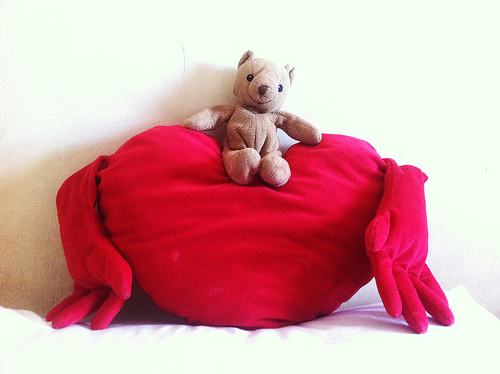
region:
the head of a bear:
[233, 30, 313, 110]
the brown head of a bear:
[205, 58, 296, 140]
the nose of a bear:
[243, 69, 280, 107]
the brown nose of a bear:
[242, 75, 282, 110]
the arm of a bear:
[176, 95, 238, 132]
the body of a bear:
[215, 4, 317, 188]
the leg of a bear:
[215, 131, 293, 186]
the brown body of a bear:
[201, 15, 313, 199]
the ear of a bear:
[233, 36, 264, 94]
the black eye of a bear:
[219, 67, 271, 105]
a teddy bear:
[203, 50, 294, 172]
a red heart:
[25, 130, 485, 326]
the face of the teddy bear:
[235, 45, 300, 111]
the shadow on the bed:
[310, 300, 405, 325]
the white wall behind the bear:
[361, 20, 471, 130]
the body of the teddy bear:
[190, 90, 320, 177]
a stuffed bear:
[195, 50, 310, 180]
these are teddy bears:
[25, 53, 471, 339]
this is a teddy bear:
[16, 115, 457, 335]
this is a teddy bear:
[188, 40, 335, 180]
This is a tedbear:
[171, 10, 330, 217]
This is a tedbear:
[173, 37, 355, 231]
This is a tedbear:
[169, 39, 341, 226]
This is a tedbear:
[177, 34, 346, 205]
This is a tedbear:
[179, 34, 334, 212]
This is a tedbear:
[180, 39, 355, 258]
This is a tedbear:
[181, 30, 340, 237]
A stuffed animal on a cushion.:
[2, 25, 487, 360]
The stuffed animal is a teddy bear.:
[180, 45, 320, 180]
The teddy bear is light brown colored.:
[175, 45, 325, 192]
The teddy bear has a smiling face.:
[220, 45, 295, 106]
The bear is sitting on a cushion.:
[182, 45, 329, 195]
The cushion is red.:
[40, 120, 455, 342]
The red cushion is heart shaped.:
[45, 120, 456, 337]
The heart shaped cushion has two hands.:
[46, 150, 456, 330]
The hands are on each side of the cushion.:
[40, 150, 455, 345]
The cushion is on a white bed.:
[8, 121, 496, 371]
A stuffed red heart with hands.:
[47, 123, 452, 330]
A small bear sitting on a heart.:
[46, 51, 455, 333]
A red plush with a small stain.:
[50, 125, 452, 332]